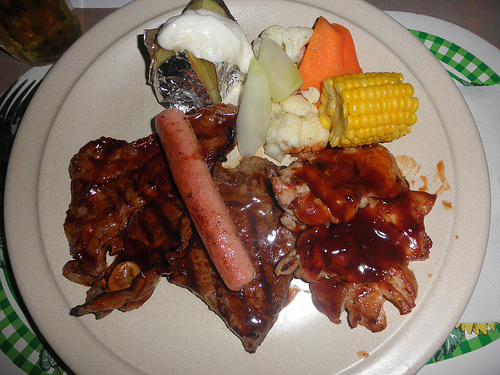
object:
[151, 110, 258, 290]
hot dog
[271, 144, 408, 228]
meat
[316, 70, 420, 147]
corn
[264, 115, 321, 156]
potato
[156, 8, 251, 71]
cream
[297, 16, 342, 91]
carrots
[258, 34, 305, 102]
vegetables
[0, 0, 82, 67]
drink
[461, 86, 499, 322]
napkin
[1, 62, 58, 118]
fork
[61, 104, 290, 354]
steak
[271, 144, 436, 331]
chicken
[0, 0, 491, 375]
plate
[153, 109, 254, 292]
food